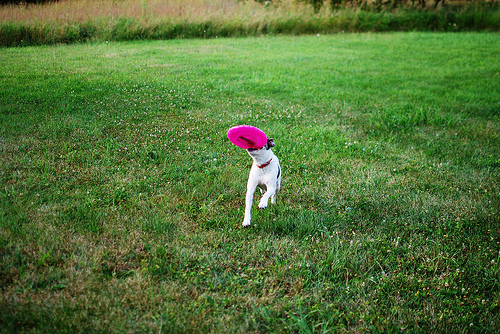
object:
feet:
[242, 172, 282, 228]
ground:
[218, 200, 299, 244]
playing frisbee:
[225, 123, 284, 229]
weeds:
[15, 9, 88, 19]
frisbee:
[226, 125, 266, 150]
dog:
[241, 124, 282, 228]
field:
[105, 36, 250, 83]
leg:
[239, 178, 256, 230]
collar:
[252, 157, 274, 168]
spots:
[101, 43, 217, 68]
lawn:
[2, 28, 476, 329]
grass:
[1, 25, 497, 330]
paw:
[242, 214, 251, 228]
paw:
[256, 195, 271, 209]